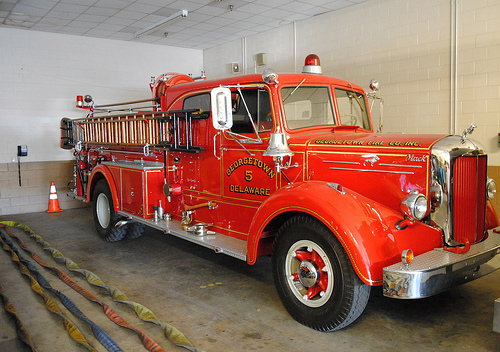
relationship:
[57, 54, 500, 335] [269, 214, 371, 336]
fire truck has a front tire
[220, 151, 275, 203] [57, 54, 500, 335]
writing on fire truck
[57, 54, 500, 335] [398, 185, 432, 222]
fire truck has a light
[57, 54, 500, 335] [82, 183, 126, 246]
fire truck has a back tire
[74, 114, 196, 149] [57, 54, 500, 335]
ladder on fire truck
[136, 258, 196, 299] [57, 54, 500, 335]
ground next to fire truck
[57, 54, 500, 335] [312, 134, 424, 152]
fire truck has words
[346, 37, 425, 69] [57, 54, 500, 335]
wall next to fire truck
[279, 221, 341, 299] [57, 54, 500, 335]
front tire of fire truck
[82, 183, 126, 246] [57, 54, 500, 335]
back tire of fire truck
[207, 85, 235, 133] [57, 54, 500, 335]
side mirror of fire truck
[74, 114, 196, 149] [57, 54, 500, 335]
ladder on side of fire truck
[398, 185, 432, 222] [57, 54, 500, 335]
light on top of fire truck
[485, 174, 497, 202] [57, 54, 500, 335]
headlight of fire truck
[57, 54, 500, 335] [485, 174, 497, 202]
fire truck has a headlight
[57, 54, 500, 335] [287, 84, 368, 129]
fire truck has windshield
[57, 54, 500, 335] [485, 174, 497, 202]
fire truck has headlight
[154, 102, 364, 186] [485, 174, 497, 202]
fire engine has headlight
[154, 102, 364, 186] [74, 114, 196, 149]
fire engine has a ladder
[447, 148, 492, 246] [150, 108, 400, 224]
grill on front of fire truck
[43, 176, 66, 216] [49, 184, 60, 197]
cone has silver stripes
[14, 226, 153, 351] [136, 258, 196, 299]
fire hoses on ground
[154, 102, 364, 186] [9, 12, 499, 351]
fire engine in garage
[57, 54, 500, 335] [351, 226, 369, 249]
fire truck for fighting fires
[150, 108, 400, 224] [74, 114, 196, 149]
fire truck has a ladder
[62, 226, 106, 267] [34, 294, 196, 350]
floor has hoses